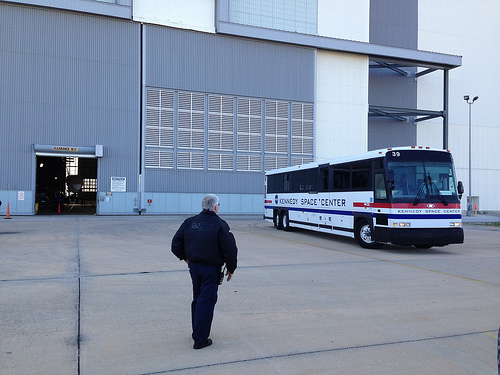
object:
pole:
[462, 94, 477, 210]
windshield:
[413, 182, 428, 207]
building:
[0, 0, 499, 217]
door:
[372, 161, 391, 228]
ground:
[3, 221, 500, 375]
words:
[279, 198, 346, 207]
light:
[462, 93, 479, 218]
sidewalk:
[461, 212, 499, 227]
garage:
[28, 142, 103, 219]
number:
[392, 151, 401, 158]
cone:
[4, 201, 12, 220]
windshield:
[430, 182, 448, 207]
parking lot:
[2, 209, 497, 370]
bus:
[262, 146, 466, 250]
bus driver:
[170, 194, 239, 351]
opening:
[35, 143, 101, 215]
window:
[144, 87, 176, 169]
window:
[177, 91, 205, 168]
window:
[208, 94, 235, 171]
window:
[237, 97, 262, 171]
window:
[265, 98, 289, 171]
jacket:
[170, 209, 239, 275]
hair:
[201, 193, 219, 211]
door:
[34, 147, 98, 217]